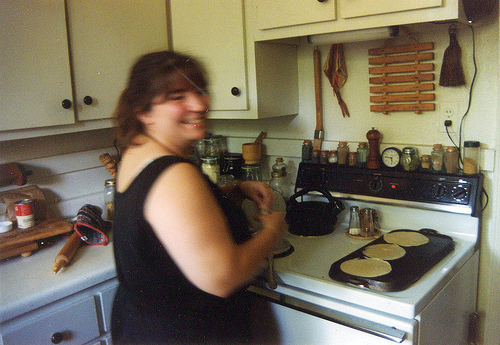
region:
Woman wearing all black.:
[98, 46, 246, 343]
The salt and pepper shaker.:
[350, 204, 384, 233]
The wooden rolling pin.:
[43, 231, 83, 269]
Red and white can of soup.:
[10, 201, 35, 231]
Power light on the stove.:
[390, 181, 396, 192]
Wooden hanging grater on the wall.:
[364, 44, 439, 119]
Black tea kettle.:
[287, 180, 342, 237]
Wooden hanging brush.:
[305, 50, 327, 158]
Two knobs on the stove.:
[432, 175, 469, 206]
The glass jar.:
[272, 153, 289, 200]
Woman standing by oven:
[99, 46, 284, 343]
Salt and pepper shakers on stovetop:
[343, 203, 383, 244]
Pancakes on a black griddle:
[326, 228, 455, 293]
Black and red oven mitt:
[68, 200, 114, 251]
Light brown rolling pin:
[44, 228, 84, 274]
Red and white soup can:
[4, 195, 44, 232]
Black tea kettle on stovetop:
[280, 181, 345, 245]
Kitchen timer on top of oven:
[373, 142, 404, 172]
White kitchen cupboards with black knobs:
[3, 1, 120, 136]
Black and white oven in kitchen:
[290, 155, 485, 343]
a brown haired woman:
[102, 47, 287, 339]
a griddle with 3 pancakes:
[328, 225, 455, 293]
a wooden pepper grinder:
[365, 125, 384, 170]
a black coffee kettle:
[280, 181, 349, 238]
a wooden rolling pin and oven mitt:
[47, 202, 114, 272]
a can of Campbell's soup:
[10, 198, 36, 233]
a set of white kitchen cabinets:
[2, 0, 463, 137]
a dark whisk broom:
[435, 29, 470, 92]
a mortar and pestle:
[237, 124, 271, 167]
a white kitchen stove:
[246, 153, 479, 342]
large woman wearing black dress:
[110, 52, 277, 344]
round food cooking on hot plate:
[325, 224, 449, 291]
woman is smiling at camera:
[123, 49, 210, 148]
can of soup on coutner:
[13, 196, 35, 230]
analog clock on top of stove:
[379, 144, 406, 172]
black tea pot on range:
[281, 184, 346, 239]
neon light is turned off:
[303, 24, 418, 51]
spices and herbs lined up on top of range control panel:
[296, 125, 483, 177]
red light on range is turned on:
[368, 171, 420, 203]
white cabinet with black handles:
[0, 1, 122, 132]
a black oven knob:
[450, 183, 465, 200]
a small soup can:
[11, 193, 36, 229]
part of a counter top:
[0, 249, 56, 323]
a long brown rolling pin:
[43, 234, 86, 276]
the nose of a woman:
[181, 93, 207, 113]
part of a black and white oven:
[256, 145, 491, 343]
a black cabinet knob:
[226, 85, 241, 97]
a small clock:
[376, 144, 405, 171]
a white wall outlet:
[435, 97, 460, 132]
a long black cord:
[452, 21, 482, 146]